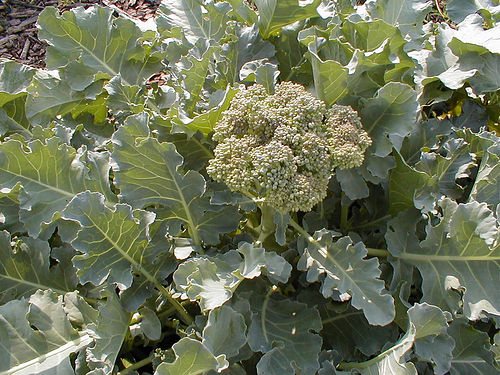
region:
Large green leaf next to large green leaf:
[295, 225, 398, 327]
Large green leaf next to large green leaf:
[232, 238, 296, 284]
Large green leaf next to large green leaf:
[107, 108, 243, 248]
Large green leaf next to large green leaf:
[61, 188, 178, 305]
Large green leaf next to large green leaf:
[0, 135, 116, 240]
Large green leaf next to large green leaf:
[391, 195, 498, 317]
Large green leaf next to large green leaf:
[244, 290, 324, 373]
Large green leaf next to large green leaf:
[30, 5, 157, 93]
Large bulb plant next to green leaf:
[207, 75, 367, 207]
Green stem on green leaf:
[157, 285, 193, 325]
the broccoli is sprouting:
[177, 65, 391, 270]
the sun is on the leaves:
[165, 243, 256, 320]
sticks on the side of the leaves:
[2, 8, 54, 63]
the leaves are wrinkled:
[154, 212, 409, 329]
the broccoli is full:
[191, 67, 381, 215]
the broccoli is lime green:
[213, 67, 383, 222]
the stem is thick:
[341, 242, 498, 269]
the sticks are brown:
[0, 15, 49, 64]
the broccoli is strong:
[190, 59, 382, 241]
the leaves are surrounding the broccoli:
[97, 12, 475, 325]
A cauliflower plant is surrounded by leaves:
[52, 15, 472, 351]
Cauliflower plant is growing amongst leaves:
[65, 20, 475, 350]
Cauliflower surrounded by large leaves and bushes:
[50, 15, 480, 351]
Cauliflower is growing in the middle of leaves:
[25, 26, 470, 356]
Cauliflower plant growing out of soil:
[55, 25, 477, 340]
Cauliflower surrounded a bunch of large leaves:
[61, 30, 476, 355]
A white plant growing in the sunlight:
[51, 22, 476, 352]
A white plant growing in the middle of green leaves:
[155, 50, 425, 265]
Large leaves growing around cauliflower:
[170, 55, 390, 255]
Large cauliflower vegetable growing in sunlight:
[167, 53, 402, 269]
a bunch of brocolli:
[202, 84, 370, 221]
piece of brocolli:
[208, 137, 262, 192]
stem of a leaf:
[158, 284, 193, 320]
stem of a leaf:
[352, 245, 389, 259]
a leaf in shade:
[299, 228, 395, 328]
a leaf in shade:
[237, 282, 325, 374]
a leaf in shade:
[383, 203, 498, 314]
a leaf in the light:
[179, 256, 242, 307]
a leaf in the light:
[171, 84, 231, 133]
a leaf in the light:
[0, 294, 90, 374]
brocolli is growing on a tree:
[218, 76, 363, 244]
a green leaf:
[110, 117, 237, 250]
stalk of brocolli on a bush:
[253, 191, 293, 242]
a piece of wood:
[18, 38, 31, 55]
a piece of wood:
[0, 32, 18, 43]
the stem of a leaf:
[288, 218, 365, 298]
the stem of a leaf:
[156, 284, 193, 326]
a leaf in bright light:
[171, 256, 249, 311]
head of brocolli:
[209, 80, 371, 239]